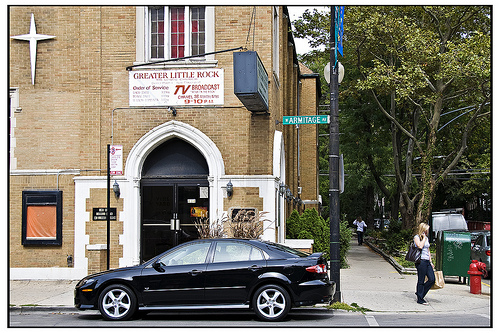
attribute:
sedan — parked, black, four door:
[74, 238, 337, 320]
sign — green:
[282, 116, 331, 125]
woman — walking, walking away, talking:
[409, 223, 435, 306]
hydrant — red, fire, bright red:
[466, 259, 484, 293]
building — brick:
[10, 2, 319, 281]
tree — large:
[354, 5, 495, 260]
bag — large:
[405, 246, 423, 261]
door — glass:
[142, 183, 175, 264]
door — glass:
[176, 186, 208, 246]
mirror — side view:
[153, 259, 163, 268]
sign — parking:
[106, 144, 125, 171]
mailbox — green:
[440, 231, 471, 283]